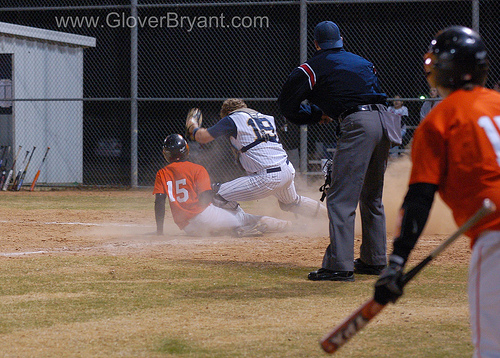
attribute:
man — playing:
[148, 126, 298, 275]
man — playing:
[372, 25, 497, 354]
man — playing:
[150, 135, 291, 252]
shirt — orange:
[405, 82, 497, 250]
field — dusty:
[33, 236, 344, 356]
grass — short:
[10, 178, 192, 210]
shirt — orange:
[152, 154, 244, 236]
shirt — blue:
[405, 72, 498, 242]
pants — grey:
[316, 102, 395, 270]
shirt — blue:
[275, 49, 381, 126]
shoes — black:
[350, 256, 384, 275]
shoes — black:
[305, 265, 358, 283]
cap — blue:
[313, 14, 344, 51]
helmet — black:
[418, 26, 496, 94]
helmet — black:
[418, 22, 493, 92]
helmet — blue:
[426, 22, 489, 89]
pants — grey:
[320, 98, 392, 281]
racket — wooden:
[293, 227, 440, 350]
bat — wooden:
[291, 225, 476, 353]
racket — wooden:
[31, 145, 54, 187]